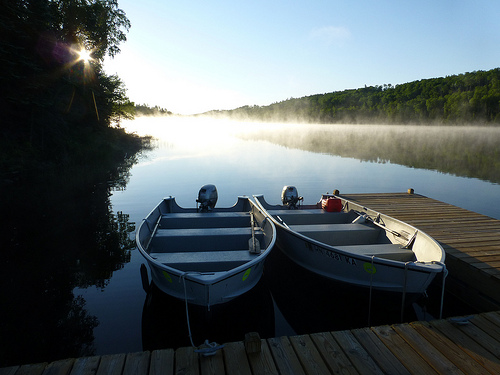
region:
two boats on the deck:
[136, 158, 478, 328]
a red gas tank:
[308, 190, 355, 219]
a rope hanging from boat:
[422, 268, 452, 328]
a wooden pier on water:
[381, 173, 496, 293]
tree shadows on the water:
[41, 125, 136, 308]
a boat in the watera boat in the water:
[279, 175, 496, 352]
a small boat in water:
[189, 194, 300, 336]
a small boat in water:
[251, 178, 494, 365]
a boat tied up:
[140, 206, 250, 326]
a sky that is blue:
[128, 8, 389, 63]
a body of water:
[132, 105, 429, 195]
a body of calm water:
[149, 99, 371, 180]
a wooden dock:
[353, 176, 498, 311]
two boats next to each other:
[115, 160, 479, 340]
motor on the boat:
[192, 175, 219, 210]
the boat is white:
[119, 175, 266, 309]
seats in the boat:
[143, 183, 257, 292]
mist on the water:
[120, 85, 482, 173]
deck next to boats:
[320, 170, 498, 325]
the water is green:
[112, 86, 485, 205]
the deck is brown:
[329, 146, 499, 283]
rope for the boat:
[158, 255, 243, 363]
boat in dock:
[135, 171, 265, 313]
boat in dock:
[281, 164, 453, 329]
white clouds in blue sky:
[180, 21, 242, 63]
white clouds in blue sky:
[315, 23, 382, 63]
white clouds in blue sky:
[172, 57, 255, 104]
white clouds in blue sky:
[240, 29, 297, 61]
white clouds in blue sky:
[404, 26, 441, 46]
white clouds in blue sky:
[132, 51, 183, 92]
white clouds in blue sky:
[220, 48, 275, 83]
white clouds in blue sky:
[255, 13, 290, 47]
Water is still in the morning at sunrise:
[94, 98, 489, 308]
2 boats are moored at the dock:
[118, 168, 451, 308]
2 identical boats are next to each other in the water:
[121, 169, 481, 330]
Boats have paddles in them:
[224, 195, 417, 259]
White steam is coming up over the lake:
[119, 110, 491, 170]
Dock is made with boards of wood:
[0, 185, 497, 373]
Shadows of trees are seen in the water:
[13, 107, 170, 346]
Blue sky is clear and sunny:
[26, 9, 496, 141]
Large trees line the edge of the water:
[186, 57, 493, 140]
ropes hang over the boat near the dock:
[130, 235, 469, 359]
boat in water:
[157, 183, 268, 290]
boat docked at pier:
[270, 145, 442, 310]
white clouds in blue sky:
[164, 0, 221, 31]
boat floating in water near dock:
[123, 183, 280, 306]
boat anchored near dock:
[250, 179, 450, 304]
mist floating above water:
[108, 98, 498, 159]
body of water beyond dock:
[63, 94, 498, 328]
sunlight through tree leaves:
[58, 30, 100, 80]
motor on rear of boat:
[184, 176, 221, 216]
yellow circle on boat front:
[358, 255, 380, 283]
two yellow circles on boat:
[154, 263, 253, 290]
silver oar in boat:
[240, 208, 261, 260]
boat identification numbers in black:
[299, 238, 361, 272]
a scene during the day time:
[13, 13, 495, 333]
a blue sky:
[96, 2, 492, 114]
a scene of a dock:
[11, 20, 484, 372]